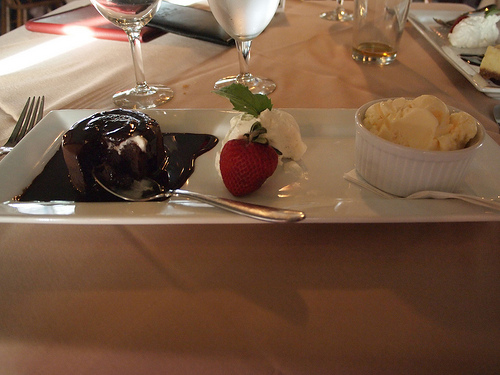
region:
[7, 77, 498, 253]
white platter on table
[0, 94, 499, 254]
white platter of deserts on table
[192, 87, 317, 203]
strawberry on platter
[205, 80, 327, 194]
whipped cream on platter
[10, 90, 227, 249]
chocolate mousse on platter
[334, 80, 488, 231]
bowl of ice cream on platter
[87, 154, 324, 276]
silver spoon on platter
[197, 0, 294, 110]
water glass on table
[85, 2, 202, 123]
wine glass on table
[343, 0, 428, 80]
empty glass on table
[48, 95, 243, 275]
Chocolate cake with chocolate sauce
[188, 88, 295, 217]
Ripe strawberry on tray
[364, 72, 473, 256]
Vanilla and ice cream in ramekin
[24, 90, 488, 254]
White rectangular ceramic tray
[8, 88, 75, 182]
Fork on the side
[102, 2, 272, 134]
Water and a wine glass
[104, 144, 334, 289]
Spoon in chocolate cake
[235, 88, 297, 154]
Whipped cream with mint a leave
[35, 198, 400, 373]
Beige tablecloth on the table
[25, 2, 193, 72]
Red tablet on the table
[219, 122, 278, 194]
large juicy looking strawberry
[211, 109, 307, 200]
strawberry and cream on a white plate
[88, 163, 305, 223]
spoon in a piece of chocolate cake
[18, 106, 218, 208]
chocolate lave cake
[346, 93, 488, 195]
small white container of vanilla ice cream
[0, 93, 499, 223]
delicious dessert on a white plate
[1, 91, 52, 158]
fork on the table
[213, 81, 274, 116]
green garnish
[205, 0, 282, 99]
cold beverage in a glass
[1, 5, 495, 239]
dessert on two white plates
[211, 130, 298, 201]
A strawberry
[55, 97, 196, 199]
A chocolate dessert.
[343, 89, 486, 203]
A bowl of ice cream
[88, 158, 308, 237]
A spoon in the cake.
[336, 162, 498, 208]
A napkin on the trey.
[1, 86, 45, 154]
A frok on the table.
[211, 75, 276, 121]
A leaf in the cream.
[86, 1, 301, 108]
A pair of wine glasses.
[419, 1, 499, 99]
Another trey of desserts.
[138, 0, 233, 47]
A blac case for the check.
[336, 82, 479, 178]
a bowl of vanilla ice cream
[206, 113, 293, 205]
a red ripe strawberry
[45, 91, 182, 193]
a piece of chocolate cake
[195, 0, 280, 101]
a glass of cold water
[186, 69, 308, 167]
a scoop of whipped cream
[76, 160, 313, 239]
a silver spoon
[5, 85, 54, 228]
a fork on the side of the plate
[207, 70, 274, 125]
a green leaf garnish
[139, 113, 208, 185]
warm chocolate sauce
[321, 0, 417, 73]
an empty clear glass